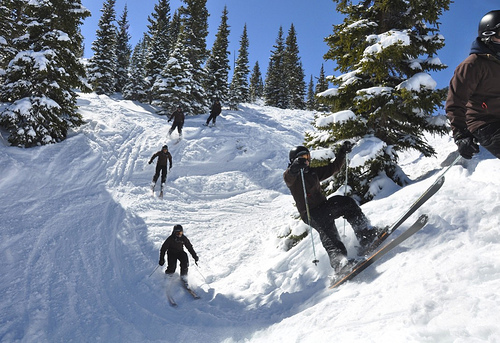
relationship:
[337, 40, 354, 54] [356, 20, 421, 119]
leaf on plant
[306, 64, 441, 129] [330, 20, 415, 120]
leaf on plant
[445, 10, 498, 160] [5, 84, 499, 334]
skier on hill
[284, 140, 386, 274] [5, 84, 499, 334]
skier on hill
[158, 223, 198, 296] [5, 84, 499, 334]
skier on hill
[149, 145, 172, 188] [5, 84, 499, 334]
skier on hill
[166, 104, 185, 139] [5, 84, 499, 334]
skier on hill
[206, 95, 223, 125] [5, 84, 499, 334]
skier on hill